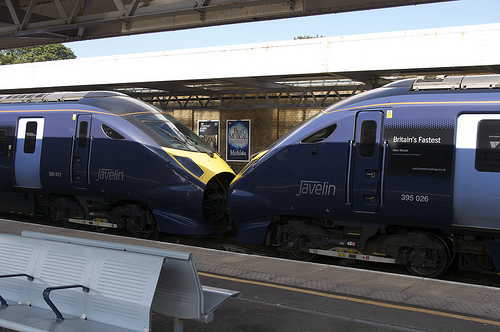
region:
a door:
[353, 113, 382, 210]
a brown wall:
[251, 110, 281, 137]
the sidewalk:
[262, 286, 359, 328]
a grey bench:
[32, 238, 162, 283]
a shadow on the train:
[92, 115, 154, 172]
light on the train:
[341, 105, 373, 132]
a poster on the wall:
[224, 120, 246, 158]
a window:
[473, 121, 498, 169]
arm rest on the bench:
[42, 280, 84, 320]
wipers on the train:
[157, 121, 196, 149]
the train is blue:
[12, 86, 419, 228]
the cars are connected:
[130, 92, 292, 290]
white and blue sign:
[225, 113, 254, 165]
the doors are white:
[452, 108, 498, 228]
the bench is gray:
[0, 236, 188, 321]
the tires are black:
[293, 227, 472, 282]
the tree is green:
[3, 42, 81, 68]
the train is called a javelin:
[283, 175, 348, 197]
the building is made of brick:
[253, 106, 286, 136]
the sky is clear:
[105, 8, 445, 48]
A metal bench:
[25, 224, 247, 326]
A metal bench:
[5, 232, 157, 329]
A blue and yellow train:
[1, 64, 498, 266]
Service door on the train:
[345, 105, 390, 224]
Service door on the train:
[69, 117, 99, 201]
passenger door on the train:
[7, 114, 64, 213]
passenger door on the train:
[441, 102, 498, 237]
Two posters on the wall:
[193, 107, 258, 166]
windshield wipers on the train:
[149, 119, 211, 159]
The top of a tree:
[1, 37, 86, 62]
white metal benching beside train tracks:
[0, 228, 227, 330]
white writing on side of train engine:
[292, 171, 347, 202]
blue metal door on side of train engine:
[346, 105, 389, 219]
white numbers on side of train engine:
[386, 186, 443, 208]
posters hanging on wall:
[193, 113, 258, 164]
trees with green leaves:
[0, 46, 85, 59]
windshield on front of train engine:
[138, 108, 215, 165]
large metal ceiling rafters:
[24, 0, 199, 36]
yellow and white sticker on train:
[381, 105, 398, 124]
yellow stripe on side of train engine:
[399, 93, 499, 111]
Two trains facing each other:
[132, 92, 338, 254]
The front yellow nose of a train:
[150, 132, 237, 195]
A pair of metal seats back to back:
[66, 240, 248, 328]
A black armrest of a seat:
[39, 280, 93, 324]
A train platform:
[277, 277, 430, 328]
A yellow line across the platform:
[303, 275, 390, 321]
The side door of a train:
[339, 102, 391, 227]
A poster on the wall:
[224, 115, 254, 166]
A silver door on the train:
[10, 108, 45, 201]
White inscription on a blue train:
[288, 167, 345, 220]